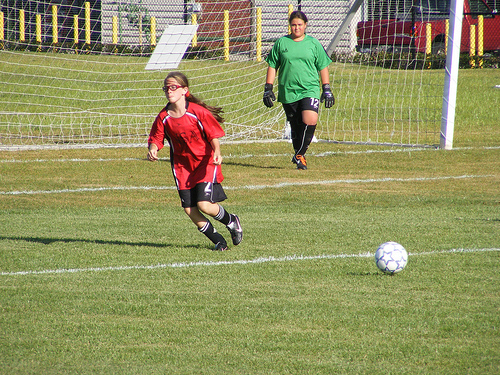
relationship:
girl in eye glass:
[144, 13, 332, 246] [162, 83, 182, 93]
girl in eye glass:
[159, 81, 186, 93] [162, 83, 182, 93]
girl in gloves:
[159, 81, 186, 93] [262, 82, 334, 106]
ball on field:
[372, 238, 408, 276] [3, 48, 496, 371]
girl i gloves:
[159, 81, 186, 93] [262, 82, 334, 106]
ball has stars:
[372, 238, 408, 276] [374, 248, 397, 269]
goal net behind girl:
[3, 1, 463, 159] [147, 71, 242, 251]